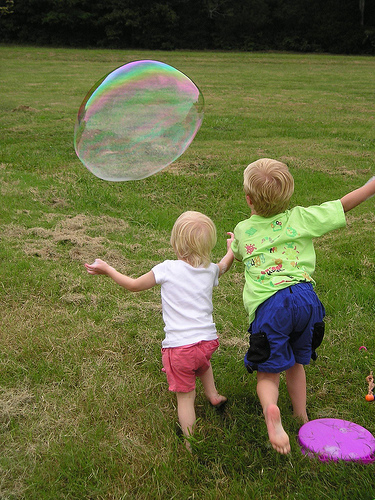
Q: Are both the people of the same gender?
A: No, they are both male and female.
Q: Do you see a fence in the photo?
A: No, there are no fences.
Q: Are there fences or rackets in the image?
A: No, there are no fences or rackets.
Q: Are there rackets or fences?
A: No, there are no fences or rackets.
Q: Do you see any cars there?
A: No, there are no cars.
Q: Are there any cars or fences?
A: No, there are no cars or fences.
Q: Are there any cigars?
A: No, there are no cigars.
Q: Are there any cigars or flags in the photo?
A: No, there are no cigars or flags.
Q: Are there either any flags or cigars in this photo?
A: No, there are no cigars or flags.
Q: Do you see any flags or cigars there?
A: No, there are no cigars or flags.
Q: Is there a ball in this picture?
A: No, there are no balls.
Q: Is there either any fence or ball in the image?
A: No, there are no balls or fences.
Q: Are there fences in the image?
A: No, there are no fences.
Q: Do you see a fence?
A: No, there are no fences.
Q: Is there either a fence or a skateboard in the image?
A: No, there are no fences or skateboards.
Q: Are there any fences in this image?
A: No, there are no fences.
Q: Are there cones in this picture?
A: No, there are no cones.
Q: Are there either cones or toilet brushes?
A: No, there are no cones or toilet brushes.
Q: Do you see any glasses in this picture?
A: No, there are no glasses.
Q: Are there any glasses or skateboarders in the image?
A: No, there are no glasses or skateboarders.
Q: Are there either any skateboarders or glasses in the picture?
A: No, there are no glasses or skateboarders.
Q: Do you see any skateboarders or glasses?
A: No, there are no glasses or skateboarders.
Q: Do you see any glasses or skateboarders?
A: No, there are no glasses or skateboarders.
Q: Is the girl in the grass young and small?
A: Yes, the girl is young and small.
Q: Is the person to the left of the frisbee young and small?
A: Yes, the girl is young and small.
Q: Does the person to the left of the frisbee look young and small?
A: Yes, the girl is young and small.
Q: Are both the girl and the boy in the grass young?
A: Yes, both the girl and the boy are young.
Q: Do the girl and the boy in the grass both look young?
A: Yes, both the girl and the boy are young.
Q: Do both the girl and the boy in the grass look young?
A: Yes, both the girl and the boy are young.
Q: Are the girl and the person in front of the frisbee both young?
A: Yes, both the girl and the boy are young.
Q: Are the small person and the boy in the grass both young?
A: Yes, both the girl and the boy are young.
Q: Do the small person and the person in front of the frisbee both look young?
A: Yes, both the girl and the boy are young.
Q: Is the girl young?
A: Yes, the girl is young.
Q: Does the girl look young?
A: Yes, the girl is young.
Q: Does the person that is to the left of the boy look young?
A: Yes, the girl is young.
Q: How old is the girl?
A: The girl is young.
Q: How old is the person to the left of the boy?
A: The girl is young.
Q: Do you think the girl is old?
A: No, the girl is young.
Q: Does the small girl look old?
A: No, the girl is young.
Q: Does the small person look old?
A: No, the girl is young.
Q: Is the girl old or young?
A: The girl is young.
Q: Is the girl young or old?
A: The girl is young.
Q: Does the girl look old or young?
A: The girl is young.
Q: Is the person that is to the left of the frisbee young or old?
A: The girl is young.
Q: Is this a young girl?
A: Yes, this is a young girl.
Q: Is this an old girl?
A: No, this is a young girl.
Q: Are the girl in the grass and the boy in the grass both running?
A: Yes, both the girl and the boy are running.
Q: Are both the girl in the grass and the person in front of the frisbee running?
A: Yes, both the girl and the boy are running.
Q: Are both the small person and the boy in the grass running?
A: Yes, both the girl and the boy are running.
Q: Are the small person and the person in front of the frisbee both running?
A: Yes, both the girl and the boy are running.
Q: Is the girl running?
A: Yes, the girl is running.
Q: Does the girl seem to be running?
A: Yes, the girl is running.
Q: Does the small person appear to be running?
A: Yes, the girl is running.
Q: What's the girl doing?
A: The girl is running.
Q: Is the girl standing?
A: No, the girl is running.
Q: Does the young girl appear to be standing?
A: No, the girl is running.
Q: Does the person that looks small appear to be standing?
A: No, the girl is running.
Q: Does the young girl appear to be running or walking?
A: The girl is running.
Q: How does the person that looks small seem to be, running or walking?
A: The girl is running.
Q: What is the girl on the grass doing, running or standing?
A: The girl is running.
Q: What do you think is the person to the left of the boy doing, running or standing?
A: The girl is running.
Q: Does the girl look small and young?
A: Yes, the girl is small and young.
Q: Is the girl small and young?
A: Yes, the girl is small and young.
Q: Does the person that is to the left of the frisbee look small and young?
A: Yes, the girl is small and young.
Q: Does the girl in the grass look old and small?
A: No, the girl is small but young.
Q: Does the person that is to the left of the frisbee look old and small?
A: No, the girl is small but young.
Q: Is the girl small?
A: Yes, the girl is small.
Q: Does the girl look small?
A: Yes, the girl is small.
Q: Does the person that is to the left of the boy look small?
A: Yes, the girl is small.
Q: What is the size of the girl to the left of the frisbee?
A: The girl is small.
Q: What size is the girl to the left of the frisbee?
A: The girl is small.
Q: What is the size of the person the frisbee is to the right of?
A: The girl is small.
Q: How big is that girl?
A: The girl is small.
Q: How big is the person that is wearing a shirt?
A: The girl is small.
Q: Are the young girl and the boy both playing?
A: Yes, both the girl and the boy are playing.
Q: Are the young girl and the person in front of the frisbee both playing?
A: Yes, both the girl and the boy are playing.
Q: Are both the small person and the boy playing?
A: Yes, both the girl and the boy are playing.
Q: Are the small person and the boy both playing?
A: Yes, both the girl and the boy are playing.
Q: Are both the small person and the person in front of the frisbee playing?
A: Yes, both the girl and the boy are playing.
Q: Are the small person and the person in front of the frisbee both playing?
A: Yes, both the girl and the boy are playing.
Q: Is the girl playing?
A: Yes, the girl is playing.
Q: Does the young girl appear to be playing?
A: Yes, the girl is playing.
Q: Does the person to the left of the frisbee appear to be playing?
A: Yes, the girl is playing.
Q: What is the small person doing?
A: The girl is playing.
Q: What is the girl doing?
A: The girl is playing.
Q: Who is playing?
A: The girl is playing.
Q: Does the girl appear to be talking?
A: No, the girl is playing.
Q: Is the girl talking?
A: No, the girl is playing.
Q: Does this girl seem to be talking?
A: No, the girl is playing.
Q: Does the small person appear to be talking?
A: No, the girl is playing.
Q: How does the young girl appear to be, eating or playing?
A: The girl is playing.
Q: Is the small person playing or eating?
A: The girl is playing.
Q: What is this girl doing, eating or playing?
A: The girl is playing.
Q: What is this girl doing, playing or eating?
A: The girl is playing.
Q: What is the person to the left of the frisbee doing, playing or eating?
A: The girl is playing.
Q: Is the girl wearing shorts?
A: Yes, the girl is wearing shorts.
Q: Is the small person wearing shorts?
A: Yes, the girl is wearing shorts.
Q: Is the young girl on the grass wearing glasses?
A: No, the girl is wearing shorts.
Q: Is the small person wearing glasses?
A: No, the girl is wearing shorts.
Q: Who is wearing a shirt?
A: The girl is wearing a shirt.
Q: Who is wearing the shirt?
A: The girl is wearing a shirt.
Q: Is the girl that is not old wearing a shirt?
A: Yes, the girl is wearing a shirt.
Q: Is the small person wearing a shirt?
A: Yes, the girl is wearing a shirt.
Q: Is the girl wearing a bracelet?
A: No, the girl is wearing a shirt.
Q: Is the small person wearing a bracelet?
A: No, the girl is wearing a shirt.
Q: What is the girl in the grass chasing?
A: The girl is chasing the bubble.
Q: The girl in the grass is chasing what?
A: The girl is chasing the bubble.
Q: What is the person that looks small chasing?
A: The girl is chasing the bubble.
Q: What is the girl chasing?
A: The girl is chasing the bubble.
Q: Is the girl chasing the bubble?
A: Yes, the girl is chasing the bubble.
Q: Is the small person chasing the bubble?
A: Yes, the girl is chasing the bubble.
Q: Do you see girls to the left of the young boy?
A: Yes, there is a girl to the left of the boy.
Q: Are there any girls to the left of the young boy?
A: Yes, there is a girl to the left of the boy.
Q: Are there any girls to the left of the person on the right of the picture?
A: Yes, there is a girl to the left of the boy.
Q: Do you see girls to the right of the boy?
A: No, the girl is to the left of the boy.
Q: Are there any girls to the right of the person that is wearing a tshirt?
A: No, the girl is to the left of the boy.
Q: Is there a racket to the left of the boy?
A: No, there is a girl to the left of the boy.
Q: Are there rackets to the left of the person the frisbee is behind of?
A: No, there is a girl to the left of the boy.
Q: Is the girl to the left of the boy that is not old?
A: Yes, the girl is to the left of the boy.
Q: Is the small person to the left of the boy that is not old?
A: Yes, the girl is to the left of the boy.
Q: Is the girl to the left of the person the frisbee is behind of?
A: Yes, the girl is to the left of the boy.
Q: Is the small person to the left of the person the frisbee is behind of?
A: Yes, the girl is to the left of the boy.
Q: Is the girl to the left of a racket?
A: No, the girl is to the left of the boy.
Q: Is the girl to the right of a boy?
A: No, the girl is to the left of a boy.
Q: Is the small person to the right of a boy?
A: No, the girl is to the left of a boy.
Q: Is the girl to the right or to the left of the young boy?
A: The girl is to the left of the boy.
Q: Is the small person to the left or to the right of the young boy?
A: The girl is to the left of the boy.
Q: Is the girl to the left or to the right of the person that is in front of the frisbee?
A: The girl is to the left of the boy.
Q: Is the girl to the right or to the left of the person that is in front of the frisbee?
A: The girl is to the left of the boy.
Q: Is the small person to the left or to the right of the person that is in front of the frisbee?
A: The girl is to the left of the boy.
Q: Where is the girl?
A: The girl is in the grass.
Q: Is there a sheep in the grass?
A: No, there is a girl in the grass.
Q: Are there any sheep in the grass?
A: No, there is a girl in the grass.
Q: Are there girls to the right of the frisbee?
A: No, the girl is to the left of the frisbee.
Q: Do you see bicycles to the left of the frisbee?
A: No, there is a girl to the left of the frisbee.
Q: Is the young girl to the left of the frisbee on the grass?
A: Yes, the girl is to the left of the frisbee.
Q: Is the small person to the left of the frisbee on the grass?
A: Yes, the girl is to the left of the frisbee.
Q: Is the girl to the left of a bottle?
A: No, the girl is to the left of the frisbee.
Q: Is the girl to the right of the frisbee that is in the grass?
A: No, the girl is to the left of the frisbee.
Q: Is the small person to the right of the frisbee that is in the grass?
A: No, the girl is to the left of the frisbee.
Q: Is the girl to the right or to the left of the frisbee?
A: The girl is to the left of the frisbee.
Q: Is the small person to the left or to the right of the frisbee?
A: The girl is to the left of the frisbee.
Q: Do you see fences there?
A: No, there are no fences.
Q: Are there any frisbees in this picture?
A: Yes, there is a frisbee.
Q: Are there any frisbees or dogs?
A: Yes, there is a frisbee.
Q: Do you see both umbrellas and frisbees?
A: No, there is a frisbee but no umbrellas.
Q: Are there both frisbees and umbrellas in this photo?
A: No, there is a frisbee but no umbrellas.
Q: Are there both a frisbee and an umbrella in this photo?
A: No, there is a frisbee but no umbrellas.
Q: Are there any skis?
A: No, there are no skis.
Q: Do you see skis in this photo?
A: No, there are no skis.